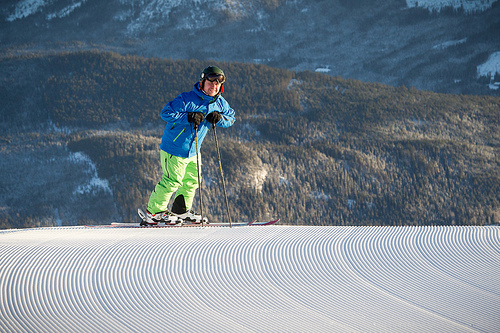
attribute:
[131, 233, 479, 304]
snow — smooth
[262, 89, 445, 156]
tree — standing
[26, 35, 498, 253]
mountain — here, covered, in background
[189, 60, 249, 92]
helmet — worn, black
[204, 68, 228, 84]
goggles — on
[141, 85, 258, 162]
jacket — blue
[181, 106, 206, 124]
gloves — black, worn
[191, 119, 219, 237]
pole — held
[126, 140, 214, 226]
pants — lime green, green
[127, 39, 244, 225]
man — skiing, smiling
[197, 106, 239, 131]
glove — black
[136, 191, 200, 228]
boot — black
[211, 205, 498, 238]
slope — down